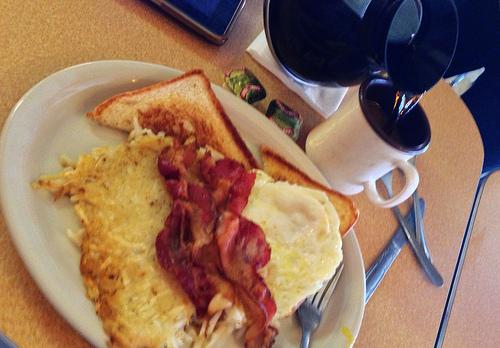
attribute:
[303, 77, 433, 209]
coffee mug — white, brown, black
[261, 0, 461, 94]
coffee pot — black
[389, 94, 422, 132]
coffee — brown, black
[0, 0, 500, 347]
table — brown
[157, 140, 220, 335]
bacon — brown, crispy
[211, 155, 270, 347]
bacon — brown, crispy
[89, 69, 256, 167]
toast — halved, brown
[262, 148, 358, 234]
toast — halved, brown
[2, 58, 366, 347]
plate — white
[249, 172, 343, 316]
egg — over medium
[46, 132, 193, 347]
hash browns — light yellow